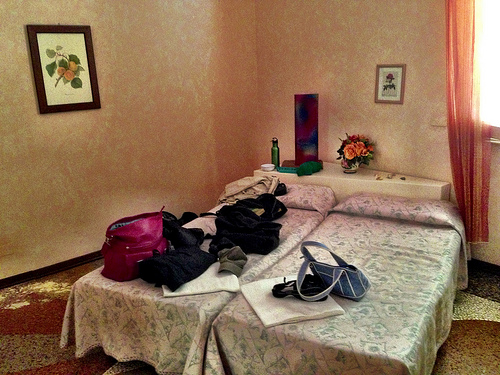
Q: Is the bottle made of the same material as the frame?
A: No, the bottle is made of glass and the frame is made of wood.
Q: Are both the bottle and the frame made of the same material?
A: No, the bottle is made of glass and the frame is made of wood.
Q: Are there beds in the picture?
A: Yes, there is a bed.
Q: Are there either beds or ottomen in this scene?
A: Yes, there is a bed.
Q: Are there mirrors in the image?
A: No, there are no mirrors.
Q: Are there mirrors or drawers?
A: No, there are no mirrors or drawers.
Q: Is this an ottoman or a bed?
A: This is a bed.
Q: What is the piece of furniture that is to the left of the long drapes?
A: The piece of furniture is a bed.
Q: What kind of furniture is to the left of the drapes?
A: The piece of furniture is a bed.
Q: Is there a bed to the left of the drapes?
A: Yes, there is a bed to the left of the drapes.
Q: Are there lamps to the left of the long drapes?
A: No, there is a bed to the left of the drapes.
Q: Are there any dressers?
A: No, there are no dressers.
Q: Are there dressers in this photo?
A: No, there are no dressers.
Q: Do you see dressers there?
A: No, there are no dressers.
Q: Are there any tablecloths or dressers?
A: No, there are no dressers or tablecloths.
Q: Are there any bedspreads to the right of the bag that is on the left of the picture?
A: Yes, there is a bedspread to the right of the bag.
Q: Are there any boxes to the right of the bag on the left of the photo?
A: No, there is a bedspread to the right of the bag.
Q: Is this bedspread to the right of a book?
A: No, the bedspread is to the right of the bag.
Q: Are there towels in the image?
A: Yes, there is a towel.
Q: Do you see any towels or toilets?
A: Yes, there is a towel.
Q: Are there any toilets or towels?
A: Yes, there is a towel.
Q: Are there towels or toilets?
A: Yes, there is a towel.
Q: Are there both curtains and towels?
A: Yes, there are both a towel and curtains.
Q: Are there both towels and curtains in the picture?
A: Yes, there are both a towel and curtains.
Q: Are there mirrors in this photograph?
A: No, there are no mirrors.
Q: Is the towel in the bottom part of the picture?
A: Yes, the towel is in the bottom of the image.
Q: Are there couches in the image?
A: No, there are no couches.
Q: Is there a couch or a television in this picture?
A: No, there are no couches or televisions.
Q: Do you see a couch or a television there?
A: No, there are no couches or televisions.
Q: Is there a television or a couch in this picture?
A: No, there are no couches or televisions.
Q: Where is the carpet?
A: The carpet is on the floor.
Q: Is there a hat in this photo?
A: Yes, there is a hat.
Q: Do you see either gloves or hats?
A: Yes, there is a hat.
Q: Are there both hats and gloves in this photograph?
A: No, there is a hat but no gloves.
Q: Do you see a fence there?
A: No, there are no fences.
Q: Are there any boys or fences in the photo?
A: No, there are no fences or boys.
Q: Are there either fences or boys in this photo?
A: No, there are no fences or boys.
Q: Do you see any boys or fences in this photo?
A: No, there are no fences or boys.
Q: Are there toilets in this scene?
A: No, there are no toilets.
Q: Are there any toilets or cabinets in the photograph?
A: No, there are no toilets or cabinets.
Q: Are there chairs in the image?
A: No, there are no chairs.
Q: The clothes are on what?
A: The clothes are on the bed.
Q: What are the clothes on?
A: The clothes are on the bed.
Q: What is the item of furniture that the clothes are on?
A: The piece of furniture is a bed.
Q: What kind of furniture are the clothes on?
A: The clothes are on the bed.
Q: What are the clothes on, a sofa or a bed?
A: The clothes are on a bed.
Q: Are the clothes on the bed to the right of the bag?
A: Yes, the clothes are on the bed.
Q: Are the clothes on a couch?
A: No, the clothes are on the bed.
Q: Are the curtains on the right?
A: Yes, the curtains are on the right of the image.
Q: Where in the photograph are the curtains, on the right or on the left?
A: The curtains are on the right of the image.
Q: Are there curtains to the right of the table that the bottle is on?
A: Yes, there are curtains to the right of the table.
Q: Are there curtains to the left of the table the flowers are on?
A: No, the curtains are to the right of the table.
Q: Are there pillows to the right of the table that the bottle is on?
A: No, there are curtains to the right of the table.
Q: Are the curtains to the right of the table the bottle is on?
A: Yes, the curtains are to the right of the table.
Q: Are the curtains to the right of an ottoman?
A: No, the curtains are to the right of the table.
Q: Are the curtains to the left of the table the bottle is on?
A: No, the curtains are to the right of the table.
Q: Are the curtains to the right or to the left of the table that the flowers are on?
A: The curtains are to the right of the table.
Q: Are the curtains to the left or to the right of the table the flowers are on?
A: The curtains are to the right of the table.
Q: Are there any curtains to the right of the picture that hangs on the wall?
A: Yes, there are curtains to the right of the picture.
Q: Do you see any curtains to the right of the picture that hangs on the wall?
A: Yes, there are curtains to the right of the picture.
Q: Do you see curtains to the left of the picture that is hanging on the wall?
A: No, the curtains are to the right of the picture.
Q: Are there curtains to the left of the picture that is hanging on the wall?
A: No, the curtains are to the right of the picture.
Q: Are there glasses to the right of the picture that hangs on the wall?
A: No, there are curtains to the right of the picture.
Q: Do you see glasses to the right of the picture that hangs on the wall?
A: No, there are curtains to the right of the picture.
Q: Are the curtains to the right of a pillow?
A: No, the curtains are to the right of a picture.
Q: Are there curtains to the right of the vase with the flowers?
A: Yes, there are curtains to the right of the vase.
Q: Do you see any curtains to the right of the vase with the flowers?
A: Yes, there are curtains to the right of the vase.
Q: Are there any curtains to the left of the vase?
A: No, the curtains are to the right of the vase.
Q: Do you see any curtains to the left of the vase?
A: No, the curtains are to the right of the vase.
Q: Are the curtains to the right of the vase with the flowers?
A: Yes, the curtains are to the right of the vase.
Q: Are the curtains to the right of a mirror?
A: No, the curtains are to the right of the vase.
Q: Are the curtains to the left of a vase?
A: No, the curtains are to the right of a vase.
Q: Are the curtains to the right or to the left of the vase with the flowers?
A: The curtains are to the right of the vase.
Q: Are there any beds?
A: Yes, there is a bed.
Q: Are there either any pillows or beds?
A: Yes, there is a bed.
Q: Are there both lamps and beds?
A: No, there is a bed but no lamps.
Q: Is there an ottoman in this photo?
A: No, there are no ottomen.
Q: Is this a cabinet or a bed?
A: This is a bed.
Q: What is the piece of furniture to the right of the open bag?
A: The piece of furniture is a bed.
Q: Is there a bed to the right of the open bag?
A: Yes, there is a bed to the right of the bag.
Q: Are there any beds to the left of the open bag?
A: No, the bed is to the right of the bag.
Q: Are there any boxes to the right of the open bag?
A: No, there is a bed to the right of the bag.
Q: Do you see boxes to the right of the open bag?
A: No, there is a bed to the right of the bag.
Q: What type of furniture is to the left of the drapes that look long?
A: The piece of furniture is a bed.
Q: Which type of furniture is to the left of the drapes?
A: The piece of furniture is a bed.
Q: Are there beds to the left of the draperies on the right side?
A: Yes, there is a bed to the left of the draperies.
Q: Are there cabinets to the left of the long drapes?
A: No, there is a bed to the left of the drapes.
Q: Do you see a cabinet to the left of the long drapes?
A: No, there is a bed to the left of the drapes.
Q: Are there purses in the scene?
A: Yes, there is a purse.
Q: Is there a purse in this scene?
A: Yes, there is a purse.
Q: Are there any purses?
A: Yes, there is a purse.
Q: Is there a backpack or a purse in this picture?
A: Yes, there is a purse.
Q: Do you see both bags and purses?
A: Yes, there are both a purse and a bag.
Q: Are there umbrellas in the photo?
A: No, there are no umbrellas.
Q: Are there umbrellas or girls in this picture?
A: No, there are no umbrellas or girls.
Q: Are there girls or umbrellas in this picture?
A: No, there are no umbrellas or girls.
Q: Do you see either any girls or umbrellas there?
A: No, there are no umbrellas or girls.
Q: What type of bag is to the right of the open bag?
A: The bag is a purse.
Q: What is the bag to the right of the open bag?
A: The bag is a purse.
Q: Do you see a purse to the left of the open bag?
A: No, the purse is to the right of the bag.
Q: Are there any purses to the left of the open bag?
A: No, the purse is to the right of the bag.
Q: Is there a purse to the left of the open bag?
A: No, the purse is to the right of the bag.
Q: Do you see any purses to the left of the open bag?
A: No, the purse is to the right of the bag.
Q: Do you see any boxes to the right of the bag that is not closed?
A: No, there is a purse to the right of the bag.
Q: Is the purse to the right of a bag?
A: Yes, the purse is to the right of a bag.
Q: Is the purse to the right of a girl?
A: No, the purse is to the right of a bag.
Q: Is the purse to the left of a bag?
A: No, the purse is to the right of a bag.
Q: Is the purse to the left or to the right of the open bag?
A: The purse is to the right of the bag.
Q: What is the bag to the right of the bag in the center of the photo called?
A: The bag is a purse.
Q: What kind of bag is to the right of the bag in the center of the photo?
A: The bag is a purse.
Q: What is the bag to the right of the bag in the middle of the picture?
A: The bag is a purse.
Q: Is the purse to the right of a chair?
A: No, the purse is to the right of the bag.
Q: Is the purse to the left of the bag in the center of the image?
A: No, the purse is to the right of the bag.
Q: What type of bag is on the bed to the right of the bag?
A: The bag is a purse.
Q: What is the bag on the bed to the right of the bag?
A: The bag is a purse.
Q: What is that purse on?
A: The purse is on the bed.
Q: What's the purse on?
A: The purse is on the bed.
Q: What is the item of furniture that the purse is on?
A: The piece of furniture is a bed.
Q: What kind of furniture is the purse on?
A: The purse is on the bed.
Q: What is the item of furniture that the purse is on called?
A: The piece of furniture is a bed.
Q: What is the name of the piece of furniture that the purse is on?
A: The piece of furniture is a bed.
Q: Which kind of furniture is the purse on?
A: The purse is on the bed.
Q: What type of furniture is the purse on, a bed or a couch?
A: The purse is on a bed.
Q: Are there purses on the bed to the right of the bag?
A: Yes, there is a purse on the bed.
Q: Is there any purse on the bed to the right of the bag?
A: Yes, there is a purse on the bed.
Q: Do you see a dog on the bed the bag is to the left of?
A: No, there is a purse on the bed.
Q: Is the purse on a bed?
A: Yes, the purse is on a bed.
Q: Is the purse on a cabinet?
A: No, the purse is on a bed.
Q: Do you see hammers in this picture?
A: No, there are no hammers.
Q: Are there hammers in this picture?
A: No, there are no hammers.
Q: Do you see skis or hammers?
A: No, there are no hammers or skis.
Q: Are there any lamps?
A: No, there are no lamps.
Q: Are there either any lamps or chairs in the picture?
A: No, there are no lamps or chairs.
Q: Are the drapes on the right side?
A: Yes, the drapes are on the right of the image.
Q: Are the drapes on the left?
A: No, the drapes are on the right of the image.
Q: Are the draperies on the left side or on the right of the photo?
A: The draperies are on the right of the image.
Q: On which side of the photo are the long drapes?
A: The draperies are on the right of the image.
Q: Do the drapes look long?
A: Yes, the drapes are long.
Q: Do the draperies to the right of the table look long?
A: Yes, the draperies are long.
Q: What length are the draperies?
A: The draperies are long.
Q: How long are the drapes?
A: The drapes are long.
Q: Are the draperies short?
A: No, the draperies are long.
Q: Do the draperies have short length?
A: No, the draperies are long.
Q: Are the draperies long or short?
A: The draperies are long.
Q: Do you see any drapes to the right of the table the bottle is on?
A: Yes, there are drapes to the right of the table.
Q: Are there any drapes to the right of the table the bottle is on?
A: Yes, there are drapes to the right of the table.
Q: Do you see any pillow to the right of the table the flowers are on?
A: No, there are drapes to the right of the table.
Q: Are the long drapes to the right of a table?
A: Yes, the drapes are to the right of a table.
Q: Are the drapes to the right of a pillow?
A: No, the drapes are to the right of a table.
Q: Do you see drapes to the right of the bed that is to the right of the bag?
A: Yes, there are drapes to the right of the bed.